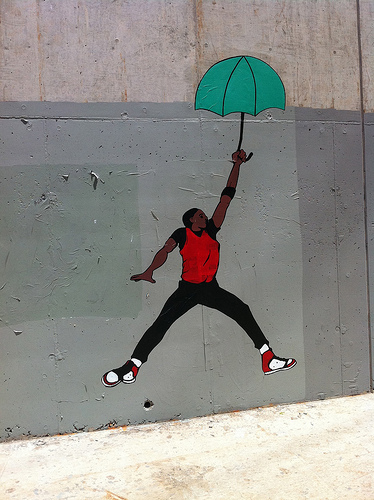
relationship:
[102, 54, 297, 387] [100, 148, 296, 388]
painting of man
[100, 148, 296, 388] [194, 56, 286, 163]
man holding umbrella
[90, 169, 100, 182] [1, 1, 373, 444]
nail sticking out of wall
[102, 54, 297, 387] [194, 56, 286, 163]
painting of umbrella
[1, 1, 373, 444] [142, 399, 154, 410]
wall has hole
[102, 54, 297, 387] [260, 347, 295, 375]
painting of sneaker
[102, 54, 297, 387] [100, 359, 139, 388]
painting of sneaker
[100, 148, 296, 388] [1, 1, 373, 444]
man painted on wall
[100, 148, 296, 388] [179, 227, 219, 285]
man wearing jersey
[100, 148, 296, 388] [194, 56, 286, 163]
man has umbrella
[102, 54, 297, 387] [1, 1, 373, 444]
painting painted over wall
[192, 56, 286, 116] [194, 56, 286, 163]
canopy of umbrella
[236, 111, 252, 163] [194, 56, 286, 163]
shaft of umbrella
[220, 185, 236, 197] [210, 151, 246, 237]
band on arm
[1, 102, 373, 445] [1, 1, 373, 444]
paint on wall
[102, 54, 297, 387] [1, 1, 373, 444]
painting on wall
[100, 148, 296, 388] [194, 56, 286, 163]
man with umbrella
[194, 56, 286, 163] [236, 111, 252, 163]
umbrella has shaft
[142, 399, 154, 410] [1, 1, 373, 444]
hole in wall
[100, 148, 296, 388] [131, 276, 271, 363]
man in pants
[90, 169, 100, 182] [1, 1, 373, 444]
nail emerging from wall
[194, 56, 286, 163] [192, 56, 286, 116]
umbrella has canopy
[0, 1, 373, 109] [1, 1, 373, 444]
top of wall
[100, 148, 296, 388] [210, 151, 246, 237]
man has arm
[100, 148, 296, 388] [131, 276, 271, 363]
man wearing pants